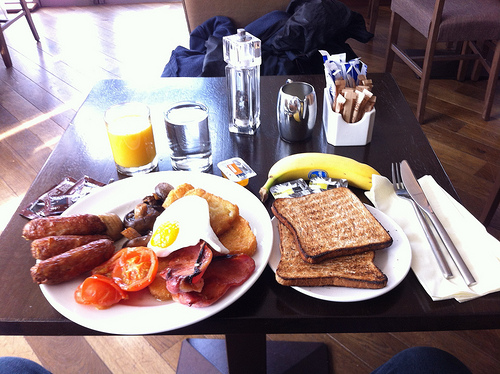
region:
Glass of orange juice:
[103, 103, 160, 175]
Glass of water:
[163, 101, 213, 171]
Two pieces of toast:
[272, 187, 394, 290]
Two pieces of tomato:
[76, 245, 156, 305]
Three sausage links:
[20, 211, 120, 281]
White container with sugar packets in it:
[321, 85, 371, 141]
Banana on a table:
[255, 150, 375, 195]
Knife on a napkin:
[400, 156, 475, 281]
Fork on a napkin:
[390, 160, 450, 280]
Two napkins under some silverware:
[366, 172, 499, 302]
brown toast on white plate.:
[268, 186, 413, 303]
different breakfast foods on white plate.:
[31, 170, 273, 324]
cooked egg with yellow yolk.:
[150, 199, 226, 261]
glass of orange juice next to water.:
[95, 100, 165, 177]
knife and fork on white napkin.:
[382, 157, 473, 296]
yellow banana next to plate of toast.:
[257, 148, 392, 202]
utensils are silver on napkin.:
[384, 147, 468, 296]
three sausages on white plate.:
[24, 205, 136, 301]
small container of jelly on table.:
[204, 158, 253, 185]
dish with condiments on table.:
[312, 49, 380, 148]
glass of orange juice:
[95, 91, 165, 178]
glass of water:
[162, 91, 236, 180]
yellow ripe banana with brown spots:
[247, 147, 397, 216]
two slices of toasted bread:
[260, 172, 398, 299]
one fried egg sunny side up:
[135, 195, 227, 270]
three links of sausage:
[23, 205, 121, 294]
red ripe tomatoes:
[55, 248, 163, 303]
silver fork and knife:
[377, 156, 474, 308]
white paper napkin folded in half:
[363, 152, 493, 322]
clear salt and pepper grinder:
[200, 21, 295, 177]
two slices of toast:
[264, 181, 391, 294]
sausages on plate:
[24, 205, 109, 276]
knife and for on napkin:
[390, 153, 476, 300]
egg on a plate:
[147, 197, 227, 253]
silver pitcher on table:
[273, 71, 321, 147]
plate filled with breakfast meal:
[23, 171, 280, 326]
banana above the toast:
[258, 148, 391, 199]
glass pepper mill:
[207, 14, 270, 146]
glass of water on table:
[161, 100, 220, 168]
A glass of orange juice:
[103, 104, 157, 176]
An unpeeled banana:
[265, 151, 384, 189]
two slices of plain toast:
[273, 199, 390, 291]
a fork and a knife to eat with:
[385, 166, 499, 283]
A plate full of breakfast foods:
[59, 166, 256, 316]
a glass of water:
[165, 96, 214, 166]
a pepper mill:
[218, 28, 267, 136]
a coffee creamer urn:
[269, 79, 321, 143]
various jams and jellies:
[268, 180, 359, 197]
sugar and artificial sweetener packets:
[319, 57, 381, 146]